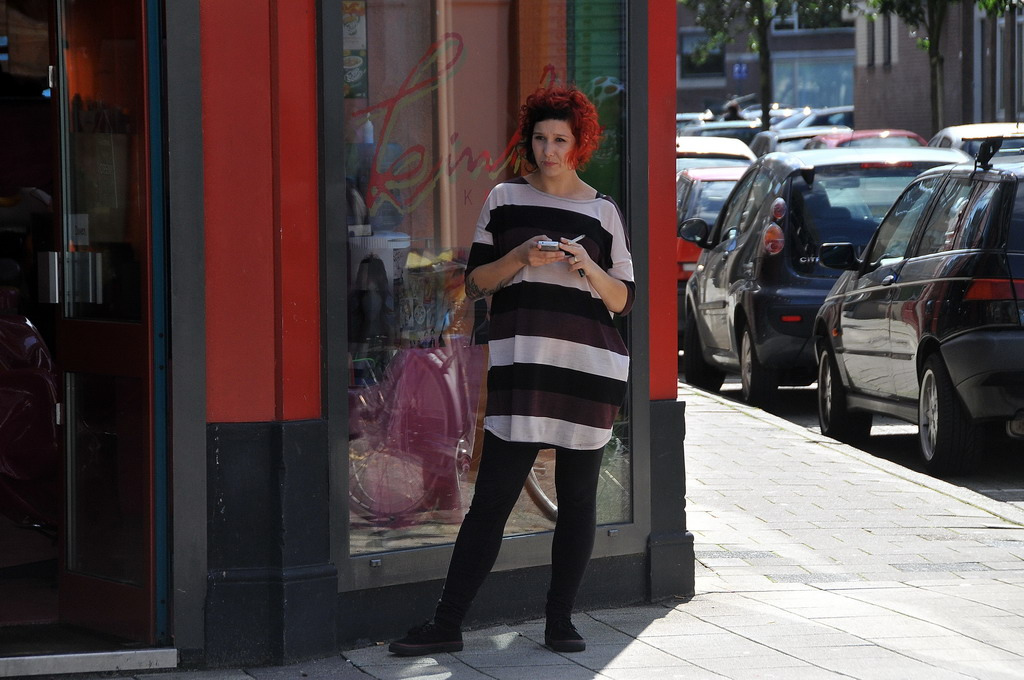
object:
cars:
[918, 119, 1024, 164]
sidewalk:
[273, 368, 1021, 679]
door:
[5, 0, 189, 677]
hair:
[502, 87, 608, 184]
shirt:
[461, 168, 639, 458]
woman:
[381, 83, 638, 659]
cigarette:
[562, 228, 592, 251]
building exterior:
[191, 4, 333, 672]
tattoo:
[455, 266, 503, 305]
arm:
[457, 225, 528, 306]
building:
[5, 0, 693, 675]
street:
[677, 3, 1022, 515]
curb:
[677, 370, 1023, 525]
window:
[331, 1, 656, 561]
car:
[803, 134, 1019, 480]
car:
[672, 162, 748, 374]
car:
[675, 137, 993, 412]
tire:
[802, 338, 885, 449]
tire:
[896, 352, 998, 487]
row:
[662, 123, 1023, 482]